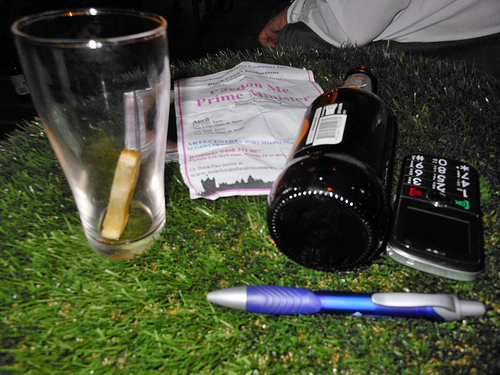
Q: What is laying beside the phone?
A: A beer bottle.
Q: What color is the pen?
A: Blue and gray.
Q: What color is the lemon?
A: Yellow.